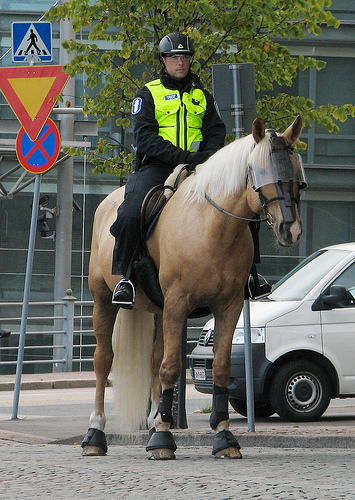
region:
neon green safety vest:
[143, 69, 215, 174]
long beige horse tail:
[109, 305, 156, 444]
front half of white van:
[194, 238, 352, 431]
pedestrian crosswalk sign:
[8, 16, 62, 68]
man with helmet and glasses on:
[151, 24, 202, 89]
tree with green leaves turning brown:
[50, 8, 152, 186]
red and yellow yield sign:
[3, 61, 79, 146]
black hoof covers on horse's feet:
[76, 418, 253, 463]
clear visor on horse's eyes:
[239, 136, 316, 196]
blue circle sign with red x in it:
[13, 114, 68, 191]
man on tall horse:
[114, 25, 239, 302]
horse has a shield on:
[238, 135, 312, 195]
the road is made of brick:
[76, 454, 329, 498]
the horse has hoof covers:
[74, 427, 246, 461]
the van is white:
[197, 250, 350, 404]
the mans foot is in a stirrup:
[103, 273, 135, 310]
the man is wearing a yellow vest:
[143, 71, 208, 158]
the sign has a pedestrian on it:
[9, 24, 50, 66]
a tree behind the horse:
[72, 0, 309, 144]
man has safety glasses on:
[165, 52, 193, 63]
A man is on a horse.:
[74, 26, 332, 461]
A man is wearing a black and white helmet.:
[148, 25, 195, 59]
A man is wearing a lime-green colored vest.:
[124, 71, 209, 159]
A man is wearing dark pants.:
[98, 152, 263, 278]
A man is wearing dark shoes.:
[94, 264, 285, 308]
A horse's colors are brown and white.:
[71, 105, 307, 460]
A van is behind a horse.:
[175, 229, 349, 420]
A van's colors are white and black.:
[183, 222, 353, 422]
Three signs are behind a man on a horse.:
[0, 13, 80, 425]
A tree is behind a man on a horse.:
[37, 0, 353, 236]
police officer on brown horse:
[84, 29, 299, 459]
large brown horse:
[74, 127, 319, 462]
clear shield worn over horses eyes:
[235, 148, 318, 197]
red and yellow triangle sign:
[4, 61, 85, 146]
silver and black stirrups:
[105, 270, 151, 323]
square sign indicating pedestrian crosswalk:
[8, 15, 62, 64]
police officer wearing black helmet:
[153, 29, 201, 63]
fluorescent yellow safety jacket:
[138, 72, 239, 167]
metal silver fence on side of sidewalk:
[8, 285, 86, 376]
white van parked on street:
[206, 232, 352, 416]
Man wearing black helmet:
[145, 38, 217, 66]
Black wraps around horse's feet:
[71, 424, 116, 451]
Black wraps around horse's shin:
[149, 374, 243, 416]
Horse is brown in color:
[79, 331, 228, 407]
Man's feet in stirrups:
[99, 262, 179, 350]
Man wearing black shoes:
[92, 252, 172, 332]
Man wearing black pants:
[79, 186, 193, 246]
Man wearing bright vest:
[150, 72, 224, 153]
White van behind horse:
[274, 269, 326, 379]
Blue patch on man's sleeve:
[122, 87, 161, 149]